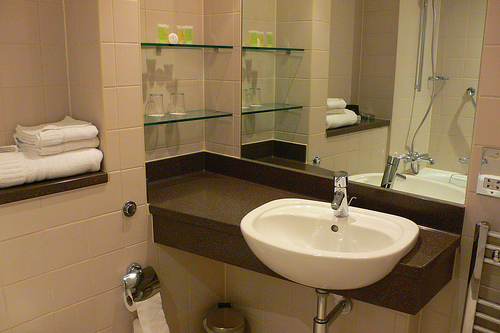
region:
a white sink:
[230, 162, 427, 305]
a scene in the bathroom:
[7, 7, 499, 320]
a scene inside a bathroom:
[14, 9, 486, 329]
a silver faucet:
[323, 157, 359, 222]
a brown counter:
[142, 145, 465, 311]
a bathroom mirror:
[223, 0, 498, 202]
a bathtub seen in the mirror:
[380, 0, 498, 200]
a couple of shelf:
[137, 20, 238, 129]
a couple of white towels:
[0, 105, 107, 185]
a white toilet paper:
[111, 245, 190, 331]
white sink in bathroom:
[236, 173, 395, 303]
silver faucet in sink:
[326, 174, 358, 236]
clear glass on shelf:
[173, 95, 190, 121]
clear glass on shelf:
[143, 94, 167, 121]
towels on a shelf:
[0, 122, 96, 177]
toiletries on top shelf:
[137, 16, 199, 48]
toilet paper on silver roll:
[115, 281, 183, 326]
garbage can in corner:
[205, 300, 255, 327]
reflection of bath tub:
[409, 76, 449, 195]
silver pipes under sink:
[297, 295, 351, 327]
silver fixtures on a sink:
[317, 165, 359, 237]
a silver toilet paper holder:
[112, 258, 162, 330]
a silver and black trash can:
[203, 294, 249, 331]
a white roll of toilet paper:
[138, 276, 169, 328]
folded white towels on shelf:
[0, 104, 97, 218]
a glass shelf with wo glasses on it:
[98, 89, 224, 151]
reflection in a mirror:
[294, 57, 464, 173]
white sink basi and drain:
[261, 204, 412, 314]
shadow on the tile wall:
[120, 55, 185, 96]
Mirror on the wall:
[240, 0, 485, 206]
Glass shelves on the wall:
[141, 39, 236, 125]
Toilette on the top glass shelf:
[157, 21, 194, 44]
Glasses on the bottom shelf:
[145, 90, 187, 115]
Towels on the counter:
[2, 115, 102, 186]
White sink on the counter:
[242, 198, 419, 287]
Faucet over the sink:
[330, 168, 349, 218]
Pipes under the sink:
[314, 292, 352, 332]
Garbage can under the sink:
[202, 300, 244, 331]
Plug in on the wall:
[475, 173, 499, 195]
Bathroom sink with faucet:
[233, 165, 420, 299]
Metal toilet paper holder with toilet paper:
[118, 261, 175, 327]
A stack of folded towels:
[0, 105, 109, 186]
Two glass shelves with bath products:
[142, 0, 237, 150]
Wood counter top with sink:
[152, 174, 454, 311]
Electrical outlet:
[474, 144, 497, 204]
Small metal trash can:
[195, 290, 254, 330]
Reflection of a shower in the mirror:
[377, 2, 468, 187]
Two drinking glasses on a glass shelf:
[131, 82, 220, 123]